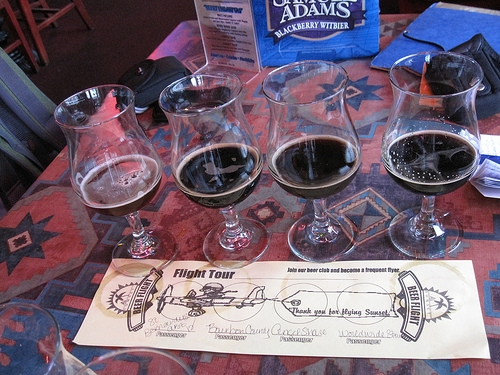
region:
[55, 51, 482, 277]
four glasses of dark liquid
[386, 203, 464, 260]
round base of glass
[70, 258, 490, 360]
illustration on rectangle paper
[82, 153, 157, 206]
foam on surface of beverage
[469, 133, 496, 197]
pages of open booklet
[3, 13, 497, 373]
geometric designs on table cloth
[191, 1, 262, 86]
card in plastic stand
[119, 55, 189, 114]
black case laying on table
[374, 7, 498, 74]
blue cover on booklet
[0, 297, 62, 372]
rim of drinking glass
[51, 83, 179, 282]
A near empty glass of wine.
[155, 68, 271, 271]
A near empty glass of wine.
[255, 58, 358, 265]
A near empty glass of wine.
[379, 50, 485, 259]
A near empty glass of wine.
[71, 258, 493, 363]
A yellow beer flight ticket.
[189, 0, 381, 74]
Samuel Adams box of blackberry witbier.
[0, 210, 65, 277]
A star pattern on the tablecloth.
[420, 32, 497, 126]
A black change purse lies on the table.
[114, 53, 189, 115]
A black phone case for an older phone.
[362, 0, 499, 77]
A blue folder sits in the background.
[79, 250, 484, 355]
The white paper in front of the glasses.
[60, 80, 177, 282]
The glass on the left.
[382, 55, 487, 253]
The glass on the right.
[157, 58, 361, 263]
The two glasses in the middle.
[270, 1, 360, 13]
The word ADAMS on the pamphlet.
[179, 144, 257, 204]
The liquid in the second glass from the left.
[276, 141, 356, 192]
The liquid in the glass in the middle.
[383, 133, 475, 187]
The liquid in the glass on the right.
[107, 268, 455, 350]
The design on the paper in front of the glasses.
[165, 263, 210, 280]
The word Flight on the paper in front of the glasses.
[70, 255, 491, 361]
cream colored paper with writing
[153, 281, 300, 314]
drawing of a man in an airplane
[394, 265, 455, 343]
black logo on paper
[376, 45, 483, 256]
glass of dark beer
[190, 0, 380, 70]
blue and white cardboard box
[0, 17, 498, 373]
patterned gaudy tablecloth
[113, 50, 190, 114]
small black leather case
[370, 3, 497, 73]
blue folder with duct tape binding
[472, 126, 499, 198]
open paper booklet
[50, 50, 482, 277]
four glasses of beer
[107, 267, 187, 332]
logo on white paper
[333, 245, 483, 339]
white paper on the surface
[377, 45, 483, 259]
the clear glass has red liquid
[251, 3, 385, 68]
the box is the color blue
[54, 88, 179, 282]
the glass is almost empty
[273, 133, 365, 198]
the liquid is a dark red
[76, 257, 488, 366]
the paper is the color cream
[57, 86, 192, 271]
a glass on the table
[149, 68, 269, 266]
a glass on the table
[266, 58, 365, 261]
a glass on the table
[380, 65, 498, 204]
a glass on the table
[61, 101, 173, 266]
a glass with wine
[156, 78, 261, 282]
a glass with wine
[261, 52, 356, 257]
a glass with wine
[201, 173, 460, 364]
a table with glasses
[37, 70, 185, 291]
A glass is on the table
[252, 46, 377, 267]
A glass is on the table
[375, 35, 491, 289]
A glass is on the table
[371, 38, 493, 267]
The glass has a brown liquid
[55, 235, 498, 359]
A flight menu is on the table